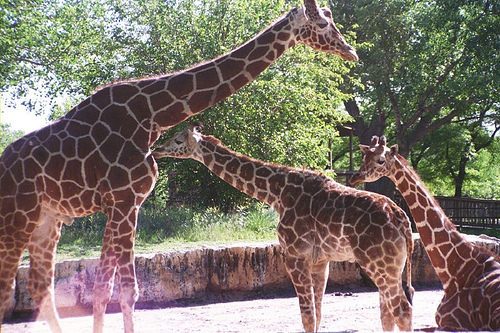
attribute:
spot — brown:
[251, 175, 270, 192]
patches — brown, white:
[96, 130, 126, 167]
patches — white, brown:
[150, 100, 189, 127]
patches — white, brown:
[126, 93, 154, 130]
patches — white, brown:
[95, 102, 140, 139]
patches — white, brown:
[166, 69, 196, 101]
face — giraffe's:
[303, 9, 362, 64]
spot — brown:
[74, 131, 97, 158]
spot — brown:
[114, 140, 148, 171]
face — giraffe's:
[154, 130, 198, 159]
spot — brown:
[256, 189, 268, 201]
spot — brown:
[253, 164, 273, 180]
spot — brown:
[415, 223, 432, 248]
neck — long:
[212, 127, 299, 204]